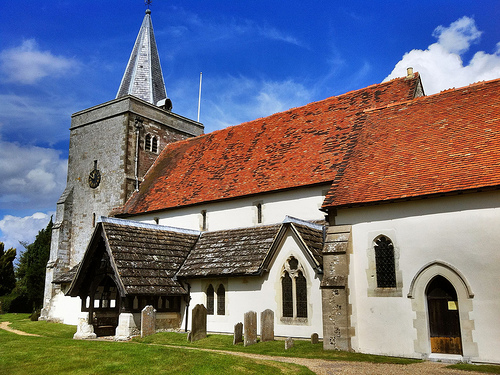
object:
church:
[37, 6, 497, 358]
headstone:
[235, 322, 243, 344]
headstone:
[244, 312, 259, 346]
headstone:
[261, 307, 274, 341]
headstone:
[283, 335, 295, 350]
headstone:
[309, 332, 320, 346]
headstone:
[189, 305, 210, 342]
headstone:
[140, 305, 157, 340]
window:
[255, 203, 261, 224]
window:
[199, 208, 205, 228]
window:
[154, 215, 159, 224]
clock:
[85, 160, 103, 192]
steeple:
[112, 0, 174, 110]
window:
[367, 231, 395, 289]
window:
[292, 272, 309, 319]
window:
[277, 274, 293, 318]